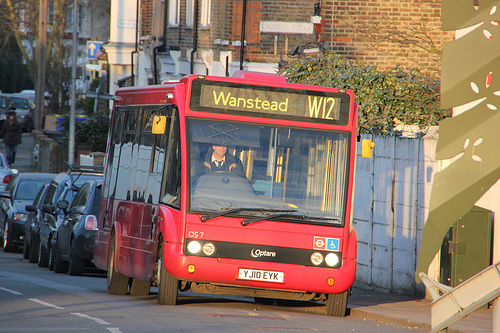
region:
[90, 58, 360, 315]
red bus on the road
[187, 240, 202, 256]
head light on the bus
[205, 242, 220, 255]
head light on the bus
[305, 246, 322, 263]
head light on the bus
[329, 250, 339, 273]
head light on the bus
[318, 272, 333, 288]
head light on the bus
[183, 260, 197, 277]
head light on the bus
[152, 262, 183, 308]
tire on the bus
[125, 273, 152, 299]
tire on the bus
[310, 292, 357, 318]
tire on the bus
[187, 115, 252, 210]
window of a vehicle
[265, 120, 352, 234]
window of a vehicle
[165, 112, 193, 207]
window of a vehicle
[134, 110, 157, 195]
window of a vehicle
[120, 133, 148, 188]
window of a vehicle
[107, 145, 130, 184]
window of a vehicle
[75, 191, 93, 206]
window of a vehicle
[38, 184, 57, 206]
window of a vehicle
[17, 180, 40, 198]
window of a vehicle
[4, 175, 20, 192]
window of a vehicle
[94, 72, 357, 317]
red passenger bus standing near curbside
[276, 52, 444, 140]
plants growing on top of concrete wall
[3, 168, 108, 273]
line up of parked car on street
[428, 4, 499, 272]
olive green artifact in the foreground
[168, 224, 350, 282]
passenger bus has lights on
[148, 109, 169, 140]
yellow rear view mirror on bus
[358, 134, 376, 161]
yellow rear view mirror on bus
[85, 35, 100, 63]
white arrow on blue sign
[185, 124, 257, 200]
man is sitting on the driver's seat of bus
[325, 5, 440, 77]
brown and tan bricks on building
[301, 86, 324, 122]
The letter is yellow.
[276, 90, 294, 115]
The letter is yellow.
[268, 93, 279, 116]
The letter is yellow.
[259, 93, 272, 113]
The letter is yellow.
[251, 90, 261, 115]
The letter is yellow.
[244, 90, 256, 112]
The letter is yellow.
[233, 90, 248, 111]
The letter is yellow.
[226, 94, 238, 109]
The letter is yellow.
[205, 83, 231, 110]
The letter is yellow.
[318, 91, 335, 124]
The number is yellow.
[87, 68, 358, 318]
Red city bus on road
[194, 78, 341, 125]
Sign on bus reading Wanstead W12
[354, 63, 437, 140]
Green bushes next to building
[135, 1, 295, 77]
Brick building in background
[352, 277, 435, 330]
Sidewalk next to road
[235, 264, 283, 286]
License plate reading YJIOEYK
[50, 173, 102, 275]
Black parked car on side of road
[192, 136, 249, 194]
Man driving a bus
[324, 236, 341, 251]
Handicap sticker on red bus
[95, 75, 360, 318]
Bus on the side of the road